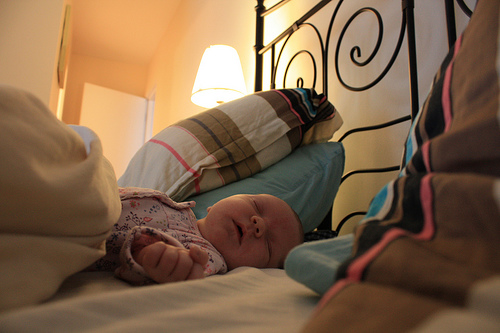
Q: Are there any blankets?
A: Yes, there is a blanket.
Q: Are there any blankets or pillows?
A: Yes, there is a blanket.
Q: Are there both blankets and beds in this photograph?
A: Yes, there are both a blanket and a bed.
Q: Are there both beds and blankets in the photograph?
A: Yes, there are both a blanket and a bed.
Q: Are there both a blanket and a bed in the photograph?
A: Yes, there are both a blanket and a bed.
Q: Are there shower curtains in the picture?
A: No, there are no shower curtains.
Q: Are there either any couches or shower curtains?
A: No, there are no shower curtains or couches.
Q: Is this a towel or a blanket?
A: This is a blanket.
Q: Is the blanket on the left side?
A: Yes, the blanket is on the left of the image.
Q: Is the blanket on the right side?
A: No, the blanket is on the left of the image.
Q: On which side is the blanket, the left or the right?
A: The blanket is on the left of the image.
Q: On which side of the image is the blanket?
A: The blanket is on the left of the image.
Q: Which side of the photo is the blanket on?
A: The blanket is on the left of the image.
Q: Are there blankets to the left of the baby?
A: Yes, there is a blanket to the left of the baby.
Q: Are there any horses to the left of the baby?
A: No, there is a blanket to the left of the baby.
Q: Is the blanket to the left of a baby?
A: Yes, the blanket is to the left of a baby.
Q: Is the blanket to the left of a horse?
A: No, the blanket is to the left of a baby.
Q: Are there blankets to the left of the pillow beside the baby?
A: Yes, there is a blanket to the left of the pillow.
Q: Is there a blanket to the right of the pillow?
A: No, the blanket is to the left of the pillow.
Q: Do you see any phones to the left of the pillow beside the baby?
A: No, there is a blanket to the left of the pillow.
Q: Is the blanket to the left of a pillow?
A: Yes, the blanket is to the left of a pillow.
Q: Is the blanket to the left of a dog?
A: No, the blanket is to the left of a pillow.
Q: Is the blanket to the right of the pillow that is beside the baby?
A: No, the blanket is to the left of the pillow.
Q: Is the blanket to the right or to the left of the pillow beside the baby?
A: The blanket is to the left of the pillow.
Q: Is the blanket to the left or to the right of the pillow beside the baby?
A: The blanket is to the left of the pillow.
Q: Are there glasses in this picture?
A: No, there are no glasses.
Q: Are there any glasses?
A: No, there are no glasses.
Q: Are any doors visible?
A: Yes, there is a door.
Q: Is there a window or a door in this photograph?
A: Yes, there is a door.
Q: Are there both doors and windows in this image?
A: No, there is a door but no windows.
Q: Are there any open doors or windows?
A: Yes, there is an open door.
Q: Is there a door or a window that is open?
A: Yes, the door is open.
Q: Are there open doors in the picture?
A: Yes, there is an open door.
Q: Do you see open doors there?
A: Yes, there is an open door.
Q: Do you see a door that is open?
A: Yes, there is an open door.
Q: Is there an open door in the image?
A: Yes, there is an open door.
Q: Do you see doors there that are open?
A: Yes, there is a door that is open.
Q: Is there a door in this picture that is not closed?
A: Yes, there is a open door.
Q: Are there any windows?
A: No, there are no windows.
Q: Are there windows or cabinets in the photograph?
A: No, there are no windows or cabinets.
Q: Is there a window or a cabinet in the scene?
A: No, there are no windows or cabinets.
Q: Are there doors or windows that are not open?
A: No, there is a door but it is open.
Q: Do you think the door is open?
A: Yes, the door is open.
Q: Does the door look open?
A: Yes, the door is open.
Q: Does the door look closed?
A: No, the door is open.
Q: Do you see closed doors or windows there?
A: No, there is a door but it is open.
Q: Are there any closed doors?
A: No, there is a door but it is open.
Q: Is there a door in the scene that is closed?
A: No, there is a door but it is open.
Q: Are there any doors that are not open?
A: No, there is a door but it is open.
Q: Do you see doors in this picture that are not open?
A: No, there is a door but it is open.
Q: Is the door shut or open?
A: The door is open.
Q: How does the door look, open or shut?
A: The door is open.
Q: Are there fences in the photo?
A: No, there are no fences.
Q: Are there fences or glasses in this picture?
A: No, there are no fences or glasses.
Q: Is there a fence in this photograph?
A: No, there are no fences.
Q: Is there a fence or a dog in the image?
A: No, there are no fences or dogs.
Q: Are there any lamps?
A: Yes, there is a lamp.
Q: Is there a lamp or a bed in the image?
A: Yes, there is a lamp.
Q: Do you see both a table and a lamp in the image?
A: No, there is a lamp but no tables.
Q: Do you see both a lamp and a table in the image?
A: No, there is a lamp but no tables.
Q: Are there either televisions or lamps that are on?
A: Yes, the lamp is on.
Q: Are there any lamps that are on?
A: Yes, there is a lamp that is on.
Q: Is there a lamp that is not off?
A: Yes, there is a lamp that is on.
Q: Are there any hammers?
A: No, there are no hammers.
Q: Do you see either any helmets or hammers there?
A: No, there are no hammers or helmets.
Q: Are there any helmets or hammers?
A: No, there are no hammers or helmets.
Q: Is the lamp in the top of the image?
A: Yes, the lamp is in the top of the image.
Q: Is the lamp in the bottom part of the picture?
A: No, the lamp is in the top of the image.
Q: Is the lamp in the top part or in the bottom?
A: The lamp is in the top of the image.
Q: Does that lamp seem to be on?
A: Yes, the lamp is on.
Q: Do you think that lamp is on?
A: Yes, the lamp is on.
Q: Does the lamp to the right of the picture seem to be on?
A: Yes, the lamp is on.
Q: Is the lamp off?
A: No, the lamp is on.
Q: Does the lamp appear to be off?
A: No, the lamp is on.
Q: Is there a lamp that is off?
A: No, there is a lamp but it is on.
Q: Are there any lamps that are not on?
A: No, there is a lamp but it is on.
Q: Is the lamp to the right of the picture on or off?
A: The lamp is on.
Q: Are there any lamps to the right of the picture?
A: Yes, there is a lamp to the right of the picture.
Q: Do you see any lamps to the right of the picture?
A: Yes, there is a lamp to the right of the picture.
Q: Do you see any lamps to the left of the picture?
A: No, the lamp is to the right of the picture.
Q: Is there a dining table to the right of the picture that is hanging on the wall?
A: No, there is a lamp to the right of the picture.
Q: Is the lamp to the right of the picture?
A: Yes, the lamp is to the right of the picture.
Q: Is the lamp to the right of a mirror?
A: No, the lamp is to the right of the picture.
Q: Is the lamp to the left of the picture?
A: No, the lamp is to the right of the picture.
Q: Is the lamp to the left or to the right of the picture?
A: The lamp is to the right of the picture.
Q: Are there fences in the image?
A: No, there are no fences.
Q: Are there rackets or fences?
A: No, there are no fences or rackets.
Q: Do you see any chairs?
A: No, there are no chairs.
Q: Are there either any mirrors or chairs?
A: No, there are no chairs or mirrors.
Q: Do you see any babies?
A: Yes, there is a baby.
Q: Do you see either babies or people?
A: Yes, there is a baby.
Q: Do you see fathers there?
A: No, there are no fathers.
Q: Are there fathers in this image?
A: No, there are no fathers.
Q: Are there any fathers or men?
A: No, there are no fathers or men.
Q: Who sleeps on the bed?
A: The baby sleeps on the bed.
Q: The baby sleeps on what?
A: The baby sleeps on the bed.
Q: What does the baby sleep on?
A: The baby sleeps on the bed.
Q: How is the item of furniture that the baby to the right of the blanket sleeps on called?
A: The piece of furniture is a bed.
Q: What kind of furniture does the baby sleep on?
A: The baby sleeps on the bed.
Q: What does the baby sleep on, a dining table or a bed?
A: The baby sleeps on a bed.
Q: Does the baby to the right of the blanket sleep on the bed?
A: Yes, the baby sleeps on the bed.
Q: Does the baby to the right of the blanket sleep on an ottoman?
A: No, the baby sleeps on the bed.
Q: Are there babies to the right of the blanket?
A: Yes, there is a baby to the right of the blanket.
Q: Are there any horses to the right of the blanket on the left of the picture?
A: No, there is a baby to the right of the blanket.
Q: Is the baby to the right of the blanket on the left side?
A: Yes, the baby is to the right of the blanket.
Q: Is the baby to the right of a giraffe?
A: No, the baby is to the right of the blanket.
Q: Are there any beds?
A: Yes, there is a bed.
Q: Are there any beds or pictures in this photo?
A: Yes, there is a bed.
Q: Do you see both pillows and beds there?
A: Yes, there are both a bed and a pillow.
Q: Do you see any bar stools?
A: No, there are no bar stools.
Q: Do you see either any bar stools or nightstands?
A: No, there are no bar stools or nightstands.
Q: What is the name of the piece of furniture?
A: The piece of furniture is a bed.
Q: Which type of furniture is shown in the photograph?
A: The furniture is a bed.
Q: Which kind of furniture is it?
A: The piece of furniture is a bed.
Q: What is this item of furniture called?
A: This is a bed.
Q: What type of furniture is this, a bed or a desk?
A: This is a bed.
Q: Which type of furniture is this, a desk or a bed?
A: This is a bed.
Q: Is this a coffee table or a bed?
A: This is a bed.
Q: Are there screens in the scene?
A: No, there are no screens.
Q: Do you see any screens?
A: No, there are no screens.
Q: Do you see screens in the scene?
A: No, there are no screens.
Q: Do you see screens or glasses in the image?
A: No, there are no screens or glasses.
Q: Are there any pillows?
A: Yes, there is a pillow.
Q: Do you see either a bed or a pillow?
A: Yes, there is a pillow.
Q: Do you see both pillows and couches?
A: No, there is a pillow but no couches.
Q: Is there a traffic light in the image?
A: No, there are no traffic lights.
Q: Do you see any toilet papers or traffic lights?
A: No, there are no traffic lights or toilet papers.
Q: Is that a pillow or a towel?
A: That is a pillow.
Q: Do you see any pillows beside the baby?
A: Yes, there is a pillow beside the baby.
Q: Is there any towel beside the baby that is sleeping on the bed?
A: No, there is a pillow beside the baby.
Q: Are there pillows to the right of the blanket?
A: Yes, there is a pillow to the right of the blanket.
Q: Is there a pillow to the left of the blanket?
A: No, the pillow is to the right of the blanket.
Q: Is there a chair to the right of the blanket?
A: No, there is a pillow to the right of the blanket.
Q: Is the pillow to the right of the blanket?
A: Yes, the pillow is to the right of the blanket.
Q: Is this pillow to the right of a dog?
A: No, the pillow is to the right of the blanket.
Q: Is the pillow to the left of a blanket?
A: No, the pillow is to the right of a blanket.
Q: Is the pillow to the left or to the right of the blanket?
A: The pillow is to the right of the blanket.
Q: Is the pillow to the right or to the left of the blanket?
A: The pillow is to the right of the blanket.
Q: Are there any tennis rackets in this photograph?
A: No, there are no tennis rackets.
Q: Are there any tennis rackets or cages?
A: No, there are no tennis rackets or cages.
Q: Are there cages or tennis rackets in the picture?
A: No, there are no tennis rackets or cages.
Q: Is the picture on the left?
A: Yes, the picture is on the left of the image.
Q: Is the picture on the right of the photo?
A: No, the picture is on the left of the image.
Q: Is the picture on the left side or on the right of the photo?
A: The picture is on the left of the image.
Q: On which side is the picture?
A: The picture is on the left of the image.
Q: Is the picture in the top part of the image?
A: Yes, the picture is in the top of the image.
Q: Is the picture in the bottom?
A: No, the picture is in the top of the image.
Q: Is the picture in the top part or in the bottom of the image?
A: The picture is in the top of the image.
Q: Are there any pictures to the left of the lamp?
A: Yes, there is a picture to the left of the lamp.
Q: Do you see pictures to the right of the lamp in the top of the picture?
A: No, the picture is to the left of the lamp.